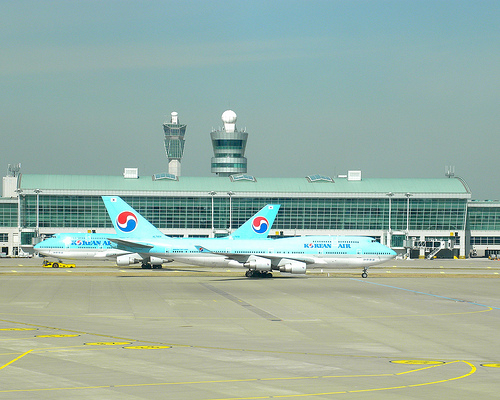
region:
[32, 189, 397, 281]
two korean air airplanes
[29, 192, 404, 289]
two airplanes pointed in opposite directions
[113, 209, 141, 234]
logo for korean air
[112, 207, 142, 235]
blue white and red circle logo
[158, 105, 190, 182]
airport control tower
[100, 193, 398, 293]
korean air airplane on tarmac at airport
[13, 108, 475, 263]
airport terminal building with control towers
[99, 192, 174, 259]
tail of korean air airplane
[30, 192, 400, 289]
two light blue jet airliners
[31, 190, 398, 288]
two passenger jets on airport tarmac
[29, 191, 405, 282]
Two light blue airplanes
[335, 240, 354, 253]
The word "AIR" on side of a plane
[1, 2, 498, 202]
The sky is clear and blue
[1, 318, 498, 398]
Yellow lines on the tarmac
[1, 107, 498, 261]
A building behind the planes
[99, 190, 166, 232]
The tail of a plane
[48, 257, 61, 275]
A round black tire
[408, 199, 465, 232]
Windows on a building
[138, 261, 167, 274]
Wheels under the plane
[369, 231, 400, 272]
The nose of a plane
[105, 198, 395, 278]
blue and white plane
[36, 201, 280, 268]
plane sitting on runway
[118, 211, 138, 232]
round decal on plane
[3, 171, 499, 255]
blue and white airport building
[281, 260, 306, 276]
white booster jet on plane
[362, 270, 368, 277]
black tire on plane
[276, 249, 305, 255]
windows on side of plane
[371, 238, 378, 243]
wind shield on plane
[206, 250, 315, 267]
wing on side of plane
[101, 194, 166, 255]
tail on back of plane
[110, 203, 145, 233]
blue red and white circle on plane tail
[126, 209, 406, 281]
the plane is blue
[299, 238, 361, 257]
blue letters on plane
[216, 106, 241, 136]
white object on tower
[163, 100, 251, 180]
towers behind the airport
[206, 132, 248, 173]
windows on the tower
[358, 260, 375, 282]
plane wheel is out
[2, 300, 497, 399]
yellow lines on the pavement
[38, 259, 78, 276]
yellow object under the plane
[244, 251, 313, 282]
plane engines are white